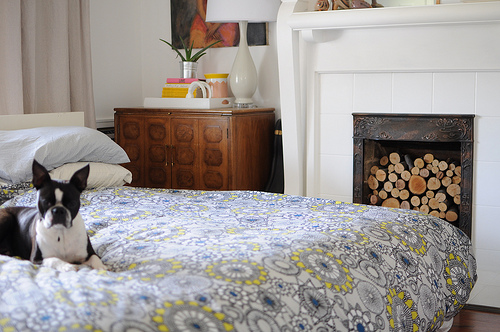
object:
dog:
[0, 158, 112, 276]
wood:
[409, 176, 425, 192]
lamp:
[203, 0, 282, 108]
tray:
[140, 98, 236, 110]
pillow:
[41, 163, 137, 191]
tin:
[181, 62, 194, 78]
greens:
[157, 38, 186, 62]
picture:
[165, 0, 274, 52]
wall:
[92, 2, 283, 105]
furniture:
[109, 107, 280, 188]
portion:
[0, 187, 479, 331]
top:
[0, 111, 87, 129]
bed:
[0, 180, 480, 331]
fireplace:
[275, 0, 499, 311]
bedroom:
[0, 0, 500, 332]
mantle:
[274, 0, 498, 28]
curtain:
[0, 0, 89, 111]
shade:
[201, 0, 282, 25]